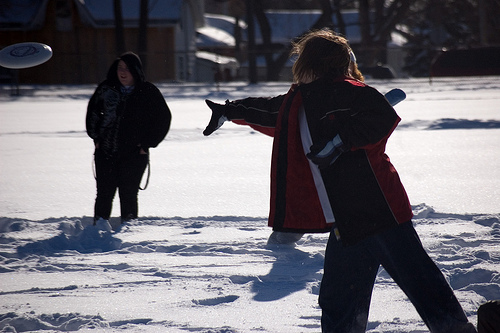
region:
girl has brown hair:
[311, 34, 361, 94]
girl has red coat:
[246, 78, 376, 286]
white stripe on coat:
[283, 113, 383, 236]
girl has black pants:
[321, 213, 456, 323]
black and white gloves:
[176, 96, 227, 148]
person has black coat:
[96, 31, 176, 234]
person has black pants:
[74, 132, 150, 219]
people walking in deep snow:
[87, 209, 395, 329]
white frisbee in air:
[1, 28, 51, 69]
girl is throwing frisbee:
[1, 22, 433, 308]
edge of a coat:
[339, 232, 369, 282]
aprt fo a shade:
[259, 260, 293, 319]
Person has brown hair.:
[290, 39, 337, 74]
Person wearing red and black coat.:
[266, 149, 298, 191]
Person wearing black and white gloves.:
[301, 125, 344, 164]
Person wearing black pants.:
[318, 259, 376, 318]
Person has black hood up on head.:
[103, 44, 180, 114]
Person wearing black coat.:
[99, 92, 184, 152]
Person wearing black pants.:
[96, 139, 159, 218]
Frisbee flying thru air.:
[16, 38, 57, 83]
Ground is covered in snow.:
[158, 228, 236, 291]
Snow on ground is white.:
[141, 240, 236, 311]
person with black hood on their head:
[88, 53, 165, 78]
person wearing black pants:
[78, 128, 154, 221]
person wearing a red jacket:
[252, 75, 419, 242]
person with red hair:
[286, 24, 350, 88]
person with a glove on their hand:
[193, 95, 231, 134]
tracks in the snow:
[428, 200, 494, 295]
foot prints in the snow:
[45, 218, 163, 286]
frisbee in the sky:
[7, 36, 53, 80]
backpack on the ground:
[476, 286, 496, 321]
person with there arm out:
[177, 76, 312, 166]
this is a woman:
[212, 87, 463, 217]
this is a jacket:
[251, 76, 363, 161]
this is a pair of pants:
[290, 269, 345, 313]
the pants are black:
[326, 251, 366, 318]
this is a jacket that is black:
[64, 105, 236, 196]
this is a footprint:
[94, 246, 247, 330]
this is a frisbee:
[33, 34, 63, 76]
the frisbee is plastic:
[7, 28, 147, 169]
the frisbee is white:
[26, 34, 74, 84]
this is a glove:
[282, 108, 419, 233]